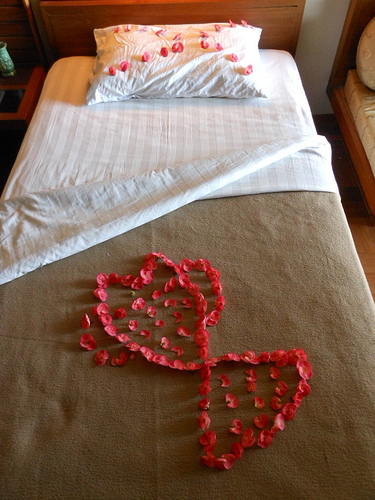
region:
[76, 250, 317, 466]
Red flower petals on bedspread.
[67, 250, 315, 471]
Flower signs making infinity sign.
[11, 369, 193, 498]
Tan bedspread on bed.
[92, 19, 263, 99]
Flower petals on white pillow.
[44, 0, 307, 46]
Brown wood headboard.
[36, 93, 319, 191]
White striped sheets on bed.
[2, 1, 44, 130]
Wood night stand by bed.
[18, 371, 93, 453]
Indention on bedspread.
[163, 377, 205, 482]
Shadow of flower petals on bed.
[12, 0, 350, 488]
Twin size bed.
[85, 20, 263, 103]
A white pillow on a bed with petals on it.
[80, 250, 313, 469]
Pink flower petals all over the bottom brown blanket on the bed.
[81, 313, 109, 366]
The three pink most left flower petals.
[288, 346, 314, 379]
The two pink most right petals.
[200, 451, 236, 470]
The two bottom most pink petals on the bed.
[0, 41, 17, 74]
A small green vase to the left of a bed.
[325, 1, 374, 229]
A barely visible other bed to the right of the flowers.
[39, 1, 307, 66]
A brown headboard behind the pillow with flowers.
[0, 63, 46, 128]
A brown side table with a vase on it.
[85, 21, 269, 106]
White pillow with flowers all over it.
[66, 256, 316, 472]
Rose petals are on the bed.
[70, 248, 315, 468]
The rose petals are pink.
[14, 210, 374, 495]
The comforter is brown.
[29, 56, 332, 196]
The sheets are white.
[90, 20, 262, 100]
The pillow is white.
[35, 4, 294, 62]
The headboard is wood.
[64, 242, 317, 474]
The petals are in a heart.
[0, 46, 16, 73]
The vase is on the night stand.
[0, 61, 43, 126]
The night stand is by the bed.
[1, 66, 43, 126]
The night stand is brown.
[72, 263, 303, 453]
red flowers on the bed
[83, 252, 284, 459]
figure eight is made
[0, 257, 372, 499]
bed covering is tan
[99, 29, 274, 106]
petals on the pillow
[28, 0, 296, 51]
headboard made of wood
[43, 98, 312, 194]
striped bed sheet on bed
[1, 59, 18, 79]
green vase on table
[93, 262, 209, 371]
heart shaped with rose petals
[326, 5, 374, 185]
bed next to bed with rose petals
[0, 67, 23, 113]
glass top on the table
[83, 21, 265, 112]
pillow on the bed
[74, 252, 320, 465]
flowers shaped like a something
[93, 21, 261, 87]
pedals on the pillowcase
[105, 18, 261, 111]
pillowcase is white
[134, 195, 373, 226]
brown cover on the bed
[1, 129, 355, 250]
sheet pulled down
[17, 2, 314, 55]
headboard on the bed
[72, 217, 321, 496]
flower pedals are red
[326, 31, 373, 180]
bed next to other bed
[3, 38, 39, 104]
table next to bed